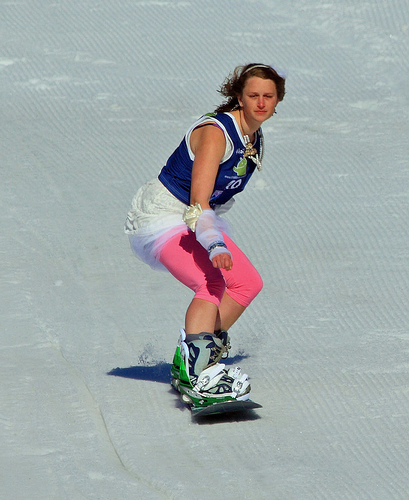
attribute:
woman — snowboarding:
[125, 62, 283, 400]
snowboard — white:
[165, 367, 264, 427]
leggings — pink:
[143, 214, 265, 311]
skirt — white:
[126, 177, 238, 252]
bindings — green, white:
[176, 349, 229, 407]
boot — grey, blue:
[188, 330, 253, 401]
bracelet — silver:
[203, 240, 229, 256]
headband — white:
[240, 64, 276, 76]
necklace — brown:
[234, 108, 261, 161]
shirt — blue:
[163, 108, 266, 207]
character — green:
[232, 156, 252, 180]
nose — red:
[256, 97, 272, 111]